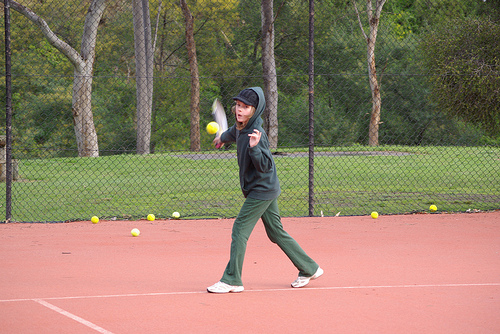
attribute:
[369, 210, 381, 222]
ball — yellow color, out of bounds, in air, colored yellow, yellow in color, yellow colored, yellow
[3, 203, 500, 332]
ground — tennis court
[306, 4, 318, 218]
pole — vertical support, metal, black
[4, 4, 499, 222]
fence — chain link, metal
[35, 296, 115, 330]
line — painted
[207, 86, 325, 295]
girl — playing tennis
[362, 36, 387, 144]
tree trunk — slightly curved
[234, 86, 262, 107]
hat — black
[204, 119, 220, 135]
ball — in play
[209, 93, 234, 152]
racket — being swung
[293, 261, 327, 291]
shoe — white